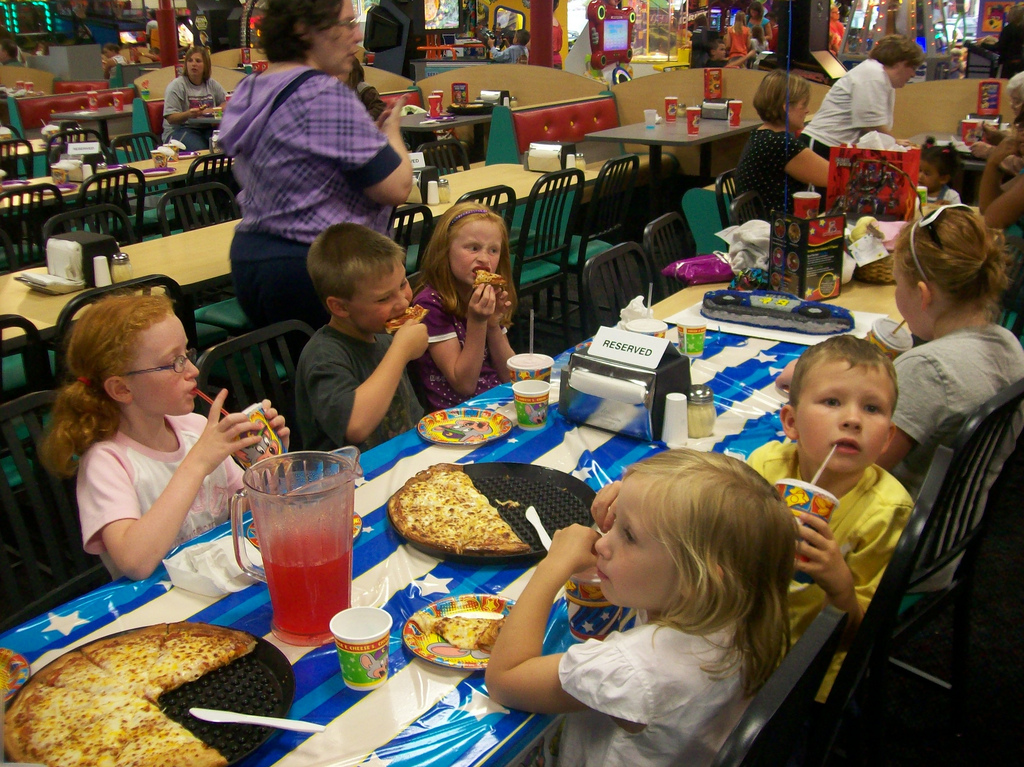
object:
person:
[410, 203, 516, 410]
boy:
[299, 219, 433, 444]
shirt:
[293, 323, 425, 450]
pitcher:
[232, 445, 361, 647]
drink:
[263, 529, 353, 645]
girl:
[488, 451, 803, 767]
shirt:
[555, 624, 750, 766]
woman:
[216, 0, 419, 368]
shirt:
[213, 63, 400, 248]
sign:
[588, 325, 671, 371]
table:
[0, 278, 1024, 767]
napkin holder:
[559, 346, 691, 443]